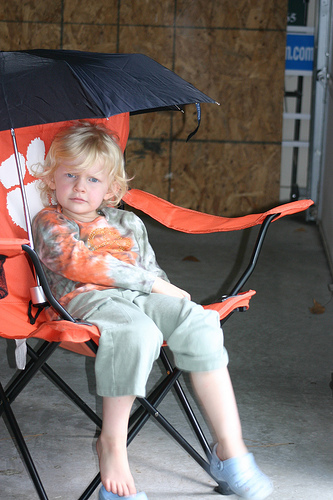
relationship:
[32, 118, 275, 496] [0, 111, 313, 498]
child sits on chair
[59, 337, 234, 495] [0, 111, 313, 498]
leg of chair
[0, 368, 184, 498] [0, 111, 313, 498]
leg of chair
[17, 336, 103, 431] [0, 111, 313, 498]
leg of chair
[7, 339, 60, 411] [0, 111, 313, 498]
leg of chair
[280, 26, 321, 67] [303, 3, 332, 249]
sign in front of door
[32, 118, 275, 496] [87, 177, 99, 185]
child has eye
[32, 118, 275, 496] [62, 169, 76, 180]
child has eye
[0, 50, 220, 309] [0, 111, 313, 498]
umbrella on chair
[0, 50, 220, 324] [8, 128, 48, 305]
umbrella has shaft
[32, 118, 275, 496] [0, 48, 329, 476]
child on chair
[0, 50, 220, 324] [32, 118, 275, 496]
umbrella on child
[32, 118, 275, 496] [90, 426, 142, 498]
child has foot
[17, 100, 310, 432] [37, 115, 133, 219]
child has hair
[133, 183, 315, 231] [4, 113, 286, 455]
restarm of chair